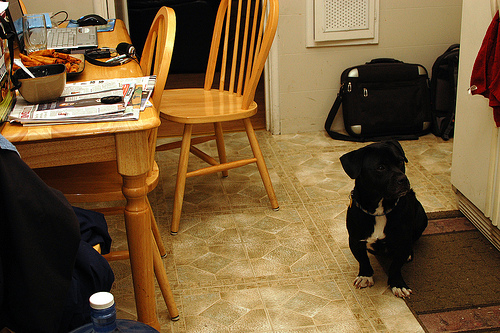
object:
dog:
[331, 139, 434, 299]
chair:
[162, 0, 284, 235]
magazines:
[17, 75, 155, 121]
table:
[0, 15, 180, 331]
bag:
[325, 58, 434, 142]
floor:
[159, 140, 459, 331]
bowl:
[17, 67, 65, 103]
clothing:
[468, 11, 499, 132]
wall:
[452, 2, 499, 250]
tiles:
[158, 136, 341, 327]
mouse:
[78, 15, 106, 27]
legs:
[159, 117, 279, 236]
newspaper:
[18, 86, 120, 116]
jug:
[64, 289, 160, 331]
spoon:
[14, 58, 36, 81]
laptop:
[4, 1, 97, 48]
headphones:
[84, 40, 133, 68]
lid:
[89, 289, 114, 308]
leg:
[118, 136, 153, 329]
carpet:
[383, 209, 499, 329]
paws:
[354, 273, 412, 296]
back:
[203, 0, 278, 110]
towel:
[465, 11, 499, 130]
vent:
[304, 0, 382, 47]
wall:
[275, 3, 461, 132]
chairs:
[35, 0, 282, 323]